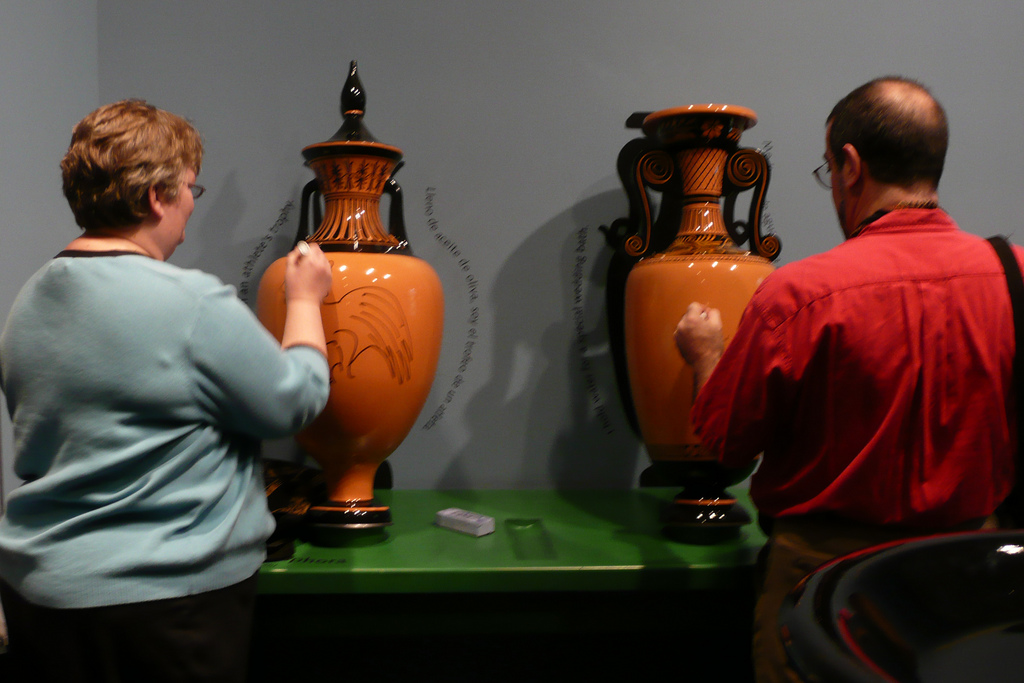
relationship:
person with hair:
[0, 98, 347, 683] [45, 83, 216, 244]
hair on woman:
[60, 111, 164, 205] [58, 108, 300, 547]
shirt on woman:
[64, 258, 402, 563] [49, 139, 324, 608]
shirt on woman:
[47, 296, 370, 577] [30, 89, 309, 507]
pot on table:
[587, 111, 856, 531] [371, 452, 810, 621]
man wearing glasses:
[669, 73, 1024, 683] [806, 152, 845, 191]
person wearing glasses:
[9, 93, 353, 679] [156, 167, 209, 206]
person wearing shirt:
[9, 93, 353, 679] [4, 249, 335, 613]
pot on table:
[244, 52, 452, 547] [6, 478, 922, 679]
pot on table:
[600, 89, 786, 541] [6, 478, 922, 679]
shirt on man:
[680, 201, 992, 552] [668, 70, 991, 678]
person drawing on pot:
[0, 98, 347, 683] [244, 52, 453, 546]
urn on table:
[588, 78, 803, 552] [6, 478, 922, 679]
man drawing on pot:
[668, 70, 991, 678] [596, 101, 785, 543]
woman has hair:
[13, 89, 310, 679] [57, 94, 191, 237]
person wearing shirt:
[0, 98, 347, 683] [0, 249, 330, 612]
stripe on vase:
[309, 180, 348, 258] [236, 50, 450, 539]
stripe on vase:
[322, 208, 348, 245] [236, 50, 450, 539]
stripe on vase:
[333, 208, 359, 247] [236, 50, 450, 539]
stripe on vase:
[322, 156, 355, 195] [236, 50, 450, 539]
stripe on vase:
[350, 158, 377, 202] [236, 50, 450, 539]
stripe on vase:
[320, 158, 355, 189] [236, 50, 450, 539]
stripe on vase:
[350, 152, 381, 194] [236, 50, 450, 539]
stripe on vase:
[359, 152, 375, 200] [236, 50, 450, 539]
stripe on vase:
[359, 163, 392, 202] [236, 50, 450, 539]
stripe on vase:
[339, 214, 361, 245] [236, 50, 450, 539]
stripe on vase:
[326, 158, 348, 197] [236, 50, 450, 539]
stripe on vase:
[333, 162, 360, 202] [236, 50, 450, 539]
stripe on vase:
[343, 156, 372, 196] [236, 50, 450, 539]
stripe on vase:
[311, 208, 344, 245] [236, 50, 450, 539]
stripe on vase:
[337, 208, 361, 247] [236, 50, 450, 539]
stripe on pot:
[320, 150, 344, 196] [244, 52, 453, 546]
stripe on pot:
[344, 150, 375, 196] [244, 52, 453, 546]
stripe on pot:
[365, 152, 389, 196] [244, 52, 453, 546]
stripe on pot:
[331, 208, 349, 245] [244, 52, 453, 546]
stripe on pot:
[348, 201, 377, 247] [244, 52, 453, 546]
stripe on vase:
[315, 156, 359, 200] [236, 50, 450, 539]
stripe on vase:
[348, 152, 375, 196] [236, 50, 450, 539]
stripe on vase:
[359, 158, 381, 195] [236, 50, 450, 539]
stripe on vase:
[337, 212, 366, 241] [236, 50, 450, 539]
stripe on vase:
[309, 201, 349, 241] [236, 50, 450, 539]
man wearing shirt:
[668, 67, 1023, 670] [669, 204, 1022, 546]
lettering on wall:
[409, 175, 489, 450] [7, 5, 1023, 500]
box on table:
[431, 497, 507, 545] [262, 476, 764, 569]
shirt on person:
[0, 249, 330, 612] [0, 98, 347, 683]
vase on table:
[236, 50, 450, 539] [245, 469, 775, 582]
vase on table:
[589, 89, 784, 535] [262, 476, 764, 569]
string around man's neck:
[861, 197, 952, 224] [841, 184, 960, 243]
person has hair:
[0, 98, 347, 683] [57, 96, 202, 233]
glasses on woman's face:
[167, 171, 213, 195] [154, 152, 207, 241]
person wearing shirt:
[0, 98, 347, 683] [4, 249, 335, 613]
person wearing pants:
[0, 98, 347, 683] [22, 562, 258, 679]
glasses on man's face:
[807, 148, 855, 187] [804, 91, 867, 234]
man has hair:
[668, 67, 1023, 670] [809, 72, 959, 207]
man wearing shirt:
[668, 67, 1023, 670] [645, 188, 1021, 519]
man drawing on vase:
[668, 67, 1023, 670] [589, 89, 784, 535]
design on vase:
[318, 281, 420, 416] [226, 52, 466, 554]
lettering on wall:
[405, 158, 492, 439] [7, 5, 1023, 500]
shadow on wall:
[437, 182, 647, 502] [7, 5, 1023, 500]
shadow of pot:
[437, 182, 647, 502] [596, 101, 785, 543]